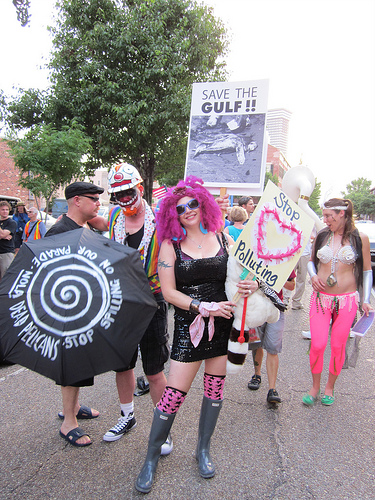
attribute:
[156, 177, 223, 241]
hair — purple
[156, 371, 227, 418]
socks — purple, pink, high, black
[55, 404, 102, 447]
sandals — paired, black, on feet, dark blue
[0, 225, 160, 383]
umbrella — large, black, white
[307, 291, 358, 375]
pants — pink, capri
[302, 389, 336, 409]
shoes — green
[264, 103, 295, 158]
building — tall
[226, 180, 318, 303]
poster — protesting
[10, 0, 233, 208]
tree — green, large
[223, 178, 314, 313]
protest sign — black, white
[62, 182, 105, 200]
cap — black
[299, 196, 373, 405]
female — protesting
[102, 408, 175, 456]
shoes — converse, black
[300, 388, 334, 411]
slippers — green, chinese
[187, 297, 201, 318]
bracelet — dark, thick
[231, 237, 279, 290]
writing — black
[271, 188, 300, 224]
writing — black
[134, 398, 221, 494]
boots — gray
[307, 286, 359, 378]
leggings — hot pink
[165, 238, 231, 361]
dress — black, sequined, tight, black sequin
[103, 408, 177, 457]
converse — black, white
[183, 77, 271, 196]
protest sign — black, white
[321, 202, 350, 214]
head band — white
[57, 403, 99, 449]
flip flops — black